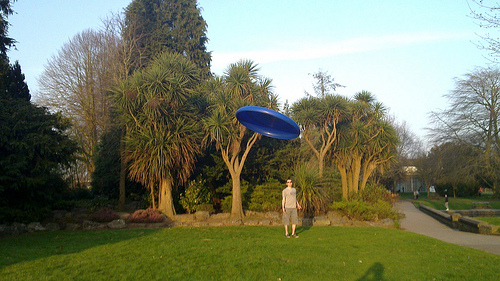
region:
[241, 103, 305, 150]
frisbee in the air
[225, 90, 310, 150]
blue frisbee in the air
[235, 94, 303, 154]
frisbee flying through air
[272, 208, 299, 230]
grey shorts on man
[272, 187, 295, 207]
grey shirt on man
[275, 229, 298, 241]
brown shoes on feet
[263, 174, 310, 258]
man standing in grass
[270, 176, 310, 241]
man standing in field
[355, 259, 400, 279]
shadow on the grass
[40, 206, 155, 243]
flower beds by grass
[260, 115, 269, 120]
part of a flier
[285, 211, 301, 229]
part of a short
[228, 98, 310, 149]
frisbee on a collision course with the photographer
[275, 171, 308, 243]
the dude who just threw the frisbee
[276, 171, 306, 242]
frisbee dude is wearing baggy shorts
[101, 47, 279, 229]
big beautiful palm trees behind frisbee dude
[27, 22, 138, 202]
leafless tree indicates it is probably wintertime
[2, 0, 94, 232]
evergreen tree off to the left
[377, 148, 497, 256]
sidewalk leading to a residence in the background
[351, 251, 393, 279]
shadow of the photographer caught on camera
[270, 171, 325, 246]
long shadow indicates it is early morning or late afternoon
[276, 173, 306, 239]
man standing in the background watching the frisbee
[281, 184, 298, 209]
gray shirt the man is wearing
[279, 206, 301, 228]
Gray shorts the man watching the frisbee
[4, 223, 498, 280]
yard that the man is standing in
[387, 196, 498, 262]
road next to yard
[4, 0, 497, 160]
blue sky with minimal cloud coverage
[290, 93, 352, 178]
tree behind the man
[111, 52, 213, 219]
tree behind the man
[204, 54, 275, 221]
tree behind the man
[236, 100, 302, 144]
Blue Frisbee in the air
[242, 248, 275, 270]
Small patch of the green grass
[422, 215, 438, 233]
Small part of the gray sidewalk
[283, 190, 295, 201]
Gray shirt of the man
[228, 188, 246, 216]
Brown oak of the tree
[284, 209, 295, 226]
Dark gray shorts of the man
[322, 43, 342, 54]
Small patch of a white cloud in the sky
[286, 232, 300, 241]
Two shoes of the man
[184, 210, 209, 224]
Gigantic rocks behind the grass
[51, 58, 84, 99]
Branches on the tree